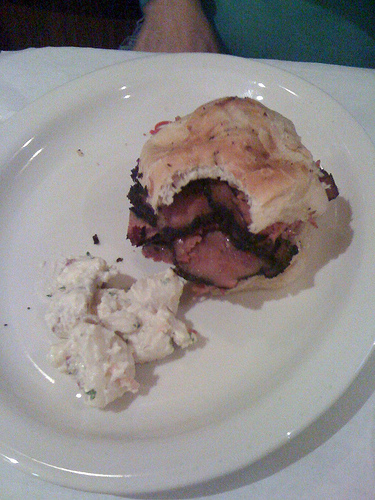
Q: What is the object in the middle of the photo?
A: Plate of food.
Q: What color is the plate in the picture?
A: White.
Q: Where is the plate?
A: Table.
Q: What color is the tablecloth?
A: White.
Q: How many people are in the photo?
A: One.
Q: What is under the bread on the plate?
A: Meat.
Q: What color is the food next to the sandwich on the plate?
A: White.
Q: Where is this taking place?
A: At a restaurant.